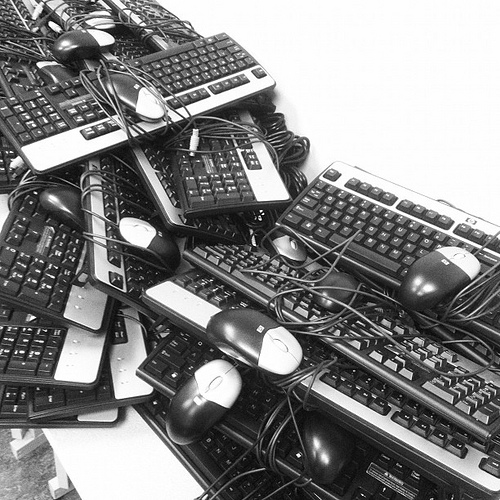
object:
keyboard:
[125, 324, 432, 496]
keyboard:
[182, 238, 500, 446]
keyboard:
[265, 150, 499, 325]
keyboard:
[158, 113, 291, 221]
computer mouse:
[150, 356, 247, 446]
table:
[38, 396, 208, 495]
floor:
[2, 425, 73, 499]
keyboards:
[147, 267, 495, 489]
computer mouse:
[97, 69, 170, 122]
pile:
[0, 0, 500, 495]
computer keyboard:
[276, 160, 500, 334]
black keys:
[27, 345, 43, 359]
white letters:
[30, 349, 41, 355]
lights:
[109, 82, 136, 108]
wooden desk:
[0, 6, 500, 498]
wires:
[77, 167, 174, 275]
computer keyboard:
[76, 145, 185, 322]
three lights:
[59, 335, 82, 373]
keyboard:
[1, 158, 113, 336]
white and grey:
[127, 89, 154, 110]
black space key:
[332, 233, 406, 269]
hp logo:
[464, 215, 477, 225]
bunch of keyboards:
[131, 158, 500, 499]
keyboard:
[1, 30, 278, 182]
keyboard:
[2, 293, 124, 391]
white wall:
[155, 0, 500, 225]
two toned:
[398, 245, 481, 311]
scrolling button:
[134, 221, 150, 236]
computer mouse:
[117, 217, 182, 259]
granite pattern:
[0, 427, 82, 499]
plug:
[187, 128, 201, 157]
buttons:
[39, 282, 53, 296]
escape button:
[324, 167, 341, 180]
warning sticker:
[366, 461, 418, 499]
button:
[118, 215, 157, 233]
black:
[116, 143, 169, 306]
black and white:
[129, 82, 157, 109]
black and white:
[94, 152, 130, 294]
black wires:
[0, 0, 205, 62]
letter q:
[324, 194, 336, 206]